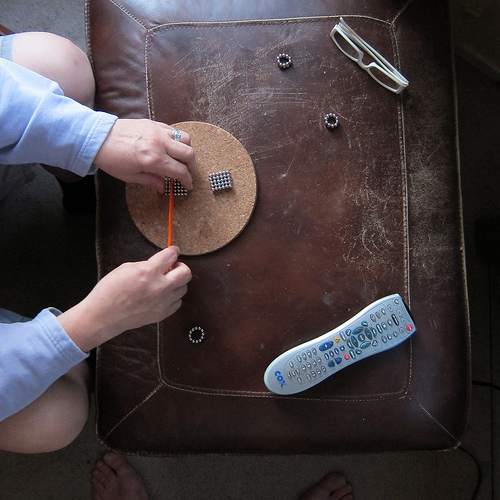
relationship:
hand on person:
[97, 115, 197, 196] [0, 31, 200, 453]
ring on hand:
[170, 127, 180, 140] [97, 115, 197, 196]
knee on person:
[33, 28, 94, 97] [11, 30, 101, 372]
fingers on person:
[145, 247, 190, 324] [0, 31, 200, 453]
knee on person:
[33, 28, 94, 97] [0, 31, 200, 453]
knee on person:
[23, 380, 91, 456] [0, 31, 200, 453]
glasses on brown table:
[325, 12, 415, 100] [82, 1, 474, 452]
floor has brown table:
[2, 2, 498, 494] [82, 1, 474, 452]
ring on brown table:
[174, 324, 209, 346] [82, 1, 474, 452]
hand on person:
[60, 246, 191, 356] [0, 31, 200, 453]